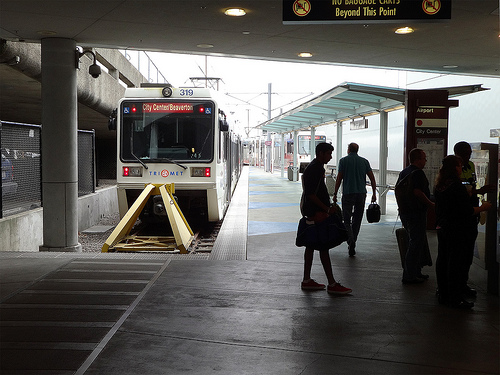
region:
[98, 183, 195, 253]
Yellow triangle barrier that keeps the train from going forward.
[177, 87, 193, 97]
Number 319 on the top right of the train.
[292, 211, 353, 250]
Duffel bag a man is carrying.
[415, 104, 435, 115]
White letters that spell AIRPORT.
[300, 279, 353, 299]
Red sneakers on a man carrying a duffel bag.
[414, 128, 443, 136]
Words that spell CITY CENTER.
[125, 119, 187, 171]
Windshield wipers on the front of a bus.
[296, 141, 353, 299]
A guy in red sneakers carrying a duffel bag.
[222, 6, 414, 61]
Three illuminated lights on a ceiling.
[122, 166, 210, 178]
Set of two lights on each side of the train.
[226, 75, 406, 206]
a train platform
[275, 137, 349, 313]
a man holding luggage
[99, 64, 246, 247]
a train parked at the station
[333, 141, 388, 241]
a man holding a bag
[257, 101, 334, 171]
a train pulling up to platform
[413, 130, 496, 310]
two people standing on platform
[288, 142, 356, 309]
a man wearing red shoes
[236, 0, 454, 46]
a sign hanging from the cieling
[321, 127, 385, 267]
a man walking away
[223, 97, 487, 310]
several people standing on platform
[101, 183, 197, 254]
Yellow train stopping device.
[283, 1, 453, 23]
Sign warning passengers to stay back.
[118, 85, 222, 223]
Tri met city passenger train.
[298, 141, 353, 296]
Train passenger carrying luggage waiting in line.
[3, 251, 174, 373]
Crosswalk lines drawn on concrete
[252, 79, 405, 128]
Glass ceiling to protect passenger from elements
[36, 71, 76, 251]
Concrete support post near the train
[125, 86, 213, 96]
Train identification number written in blue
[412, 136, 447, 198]
Train time schedule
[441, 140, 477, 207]
Train worker helping out train riders.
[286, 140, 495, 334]
people at a train station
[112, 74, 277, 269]
train at the station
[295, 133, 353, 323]
a man carrying bags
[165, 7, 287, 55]
the roof has lights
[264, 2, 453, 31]
the ceiling has a sign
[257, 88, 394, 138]
the roof is green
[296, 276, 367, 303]
this man has tennis shoes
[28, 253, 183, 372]
there are lines on the concrete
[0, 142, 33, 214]
a car behind a fence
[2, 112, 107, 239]
a black fence on concrete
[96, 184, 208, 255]
yellow mechanism on train tracks to stop train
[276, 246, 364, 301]
two legs in shadow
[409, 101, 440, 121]
white lettered airport sign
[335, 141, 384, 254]
man walking away holding bag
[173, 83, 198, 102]
black numbered 319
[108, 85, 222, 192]
front of train with four red lights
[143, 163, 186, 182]
blue lettered Tri Met sign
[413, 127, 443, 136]
white lettered City Center sign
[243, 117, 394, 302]
two men on train platform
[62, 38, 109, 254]
camera suspended from white column